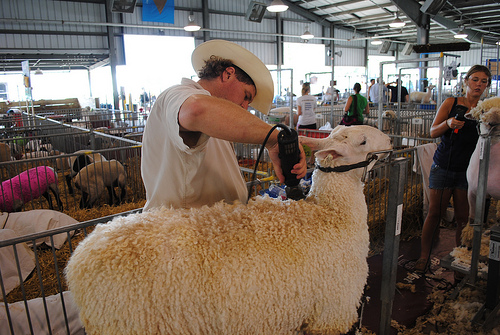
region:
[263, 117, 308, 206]
Black electric shears being used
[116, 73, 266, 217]
White shirt on man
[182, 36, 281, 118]
White hat on man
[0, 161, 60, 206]
Pink blanket on animal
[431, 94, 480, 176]
Blue tank top on woman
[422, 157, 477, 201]
blue jean shorts on woman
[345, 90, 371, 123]
Green shirt on person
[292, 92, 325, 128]
White shirt on person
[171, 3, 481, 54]
Ceiling hanging lights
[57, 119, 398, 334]
White and brown animal being sheared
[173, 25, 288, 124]
a man wearing a cowboy hat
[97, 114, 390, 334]
a white sheep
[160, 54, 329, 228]
a man holding a set of clippers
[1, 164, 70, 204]
a sheep with a pink cover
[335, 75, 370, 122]
a woman wearing a green shirt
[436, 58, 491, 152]
a woman wearing a black shirt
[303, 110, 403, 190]
a sheep with a harness on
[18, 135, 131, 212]
a metal gate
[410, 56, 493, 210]
a woman wearing blue jean shorts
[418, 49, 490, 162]
a woman holding a set of clippers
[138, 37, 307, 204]
A man wearing a cowboy hat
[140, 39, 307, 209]
A man using clippers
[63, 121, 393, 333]
A sheep that's being sheared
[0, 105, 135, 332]
Sheep in holding pins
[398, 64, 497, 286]
A woman that's shearing a sheep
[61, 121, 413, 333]
A sheep being held in place by a leash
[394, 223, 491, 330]
Wool from a sheared sheep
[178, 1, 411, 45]
Lights hanging from the ceiling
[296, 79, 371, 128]
Two people looking at sheep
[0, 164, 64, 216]
A sheep wearing pink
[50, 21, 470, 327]
A person is shearing an animal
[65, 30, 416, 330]
A person is using shearing clippers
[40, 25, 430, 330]
Person shearing wool from an animal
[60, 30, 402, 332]
An animal is allowing itself to be sheared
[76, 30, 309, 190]
A person is wearing a hat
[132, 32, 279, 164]
A person has brown colored hair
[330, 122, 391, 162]
Head of a large animal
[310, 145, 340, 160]
Ear of a large animal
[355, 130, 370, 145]
Eye of a large animal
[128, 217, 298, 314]
Fur of a large animal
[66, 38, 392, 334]
a man sheering a lamb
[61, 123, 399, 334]
a white lamb stading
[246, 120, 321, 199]
electric black shaver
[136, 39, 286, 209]
a man wearing a white hat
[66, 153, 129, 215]
a shaved lamb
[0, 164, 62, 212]
a lamb with a pink sweater on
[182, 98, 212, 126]
a man's elbow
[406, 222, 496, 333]
left over pieces of lamb wool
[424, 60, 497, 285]
a woman sheering a lamb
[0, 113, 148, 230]
a lamb steel pin